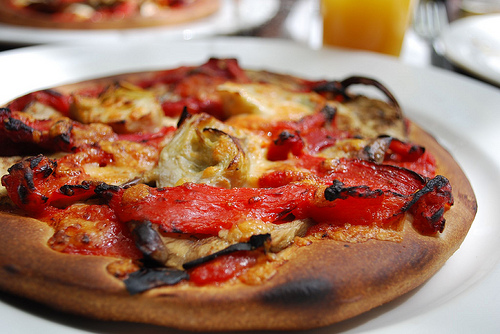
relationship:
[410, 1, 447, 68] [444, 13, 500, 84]
fork sitting beside plate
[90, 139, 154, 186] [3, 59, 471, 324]
cheese on top of pizza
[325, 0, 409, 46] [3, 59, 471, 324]
juice sitting behind pizza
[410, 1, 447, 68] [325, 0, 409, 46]
fork sitting beside juice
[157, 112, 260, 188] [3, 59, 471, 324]
artichoke on top of pizza